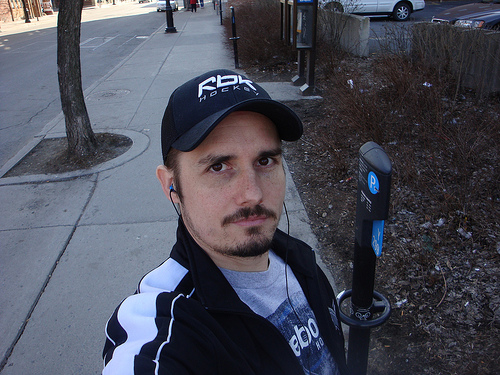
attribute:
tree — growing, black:
[32, 18, 113, 172]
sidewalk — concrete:
[5, 30, 209, 311]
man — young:
[75, 34, 352, 375]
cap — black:
[144, 51, 323, 161]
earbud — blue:
[158, 177, 201, 212]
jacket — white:
[85, 237, 363, 373]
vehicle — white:
[320, 0, 441, 40]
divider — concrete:
[268, 16, 380, 53]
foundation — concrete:
[257, 64, 326, 107]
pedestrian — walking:
[185, 3, 204, 13]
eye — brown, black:
[195, 138, 239, 182]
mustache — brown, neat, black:
[216, 205, 283, 223]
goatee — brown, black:
[219, 228, 285, 260]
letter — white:
[188, 63, 246, 104]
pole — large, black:
[323, 119, 417, 371]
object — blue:
[340, 175, 391, 207]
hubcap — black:
[326, 258, 424, 333]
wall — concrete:
[318, 12, 382, 54]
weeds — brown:
[326, 62, 426, 126]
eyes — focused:
[189, 148, 286, 182]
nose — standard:
[233, 170, 277, 213]